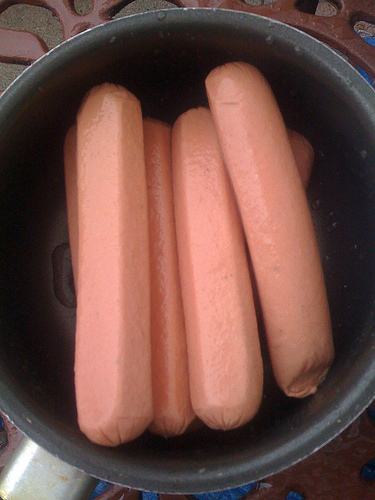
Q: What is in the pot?
A: Hot dogs.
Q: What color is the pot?
A: Black.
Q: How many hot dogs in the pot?
A: Six.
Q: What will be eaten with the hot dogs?
A: Hot dog buns.